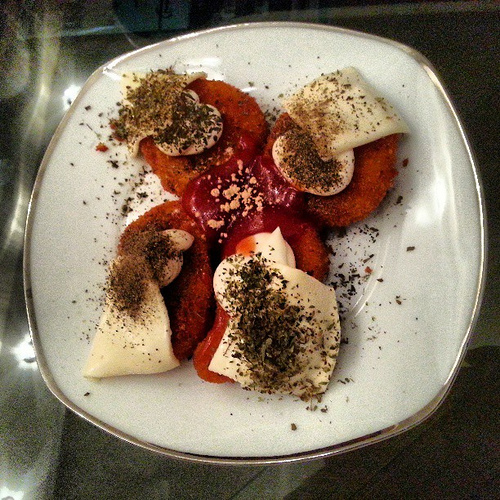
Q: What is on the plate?
A: Food.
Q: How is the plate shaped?
A: It is squared.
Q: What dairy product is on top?
A: Cheese.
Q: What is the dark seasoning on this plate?
A: Pepper.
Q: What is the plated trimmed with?
A: Silver.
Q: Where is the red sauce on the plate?
A: In the center.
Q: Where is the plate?
A: On the granite.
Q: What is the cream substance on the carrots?
A: Sour cream.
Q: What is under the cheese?
A: Carrots.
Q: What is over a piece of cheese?
A: Spices.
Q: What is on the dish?
A: Spices.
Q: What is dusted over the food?
A: Black pepper.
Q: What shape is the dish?
A: Square.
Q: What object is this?
A: A white plate with a silver edge.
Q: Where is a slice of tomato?
A: On a white plate.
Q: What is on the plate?
A: A slice of white cheese.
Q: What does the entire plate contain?
A: Tomatoes and cheese.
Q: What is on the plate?
A: Food.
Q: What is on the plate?
A: Yams, cheese, pepper.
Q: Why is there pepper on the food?
A: For flavor.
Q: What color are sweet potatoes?
A: Dark orange.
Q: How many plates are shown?
A: One.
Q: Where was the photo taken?
A: Table.